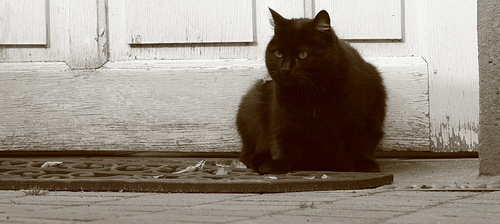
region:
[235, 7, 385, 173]
the cat lying down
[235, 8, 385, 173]
the black cat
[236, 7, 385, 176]
the cat all alone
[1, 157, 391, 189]
the mat under the cat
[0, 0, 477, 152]
the wood behind the cat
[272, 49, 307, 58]
the eyes on the cat's face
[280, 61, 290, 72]
the nose on the cat's face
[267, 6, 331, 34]
the ears on the cat's head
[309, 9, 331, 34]
the ear on the cat's head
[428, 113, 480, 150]
the paint chipped off the wood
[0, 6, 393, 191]
Black cat sitting on a door mat.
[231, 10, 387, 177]
the black cat laying in front of the door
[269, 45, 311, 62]
the green eyes of the cat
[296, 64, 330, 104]
the whiskers ont he cats face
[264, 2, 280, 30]
hair in the ear of the cat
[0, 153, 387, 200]
the black placemat in front of the door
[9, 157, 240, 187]
the paper on the black doormat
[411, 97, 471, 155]
the white paint chipping off the door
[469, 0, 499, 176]
the cement wall next to the front door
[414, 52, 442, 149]
the line in the door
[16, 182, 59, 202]
the grass growing on the porch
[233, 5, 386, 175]
A cat on a mat.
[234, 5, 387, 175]
A cat by a door.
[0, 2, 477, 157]
Part of a door.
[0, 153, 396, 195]
A mat by a door.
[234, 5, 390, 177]
A black cat sitting down.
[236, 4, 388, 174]
A black cat by a door.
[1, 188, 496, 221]
Bricks on the ground.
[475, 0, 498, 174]
Part of a wall.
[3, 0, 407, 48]
Panels on a door.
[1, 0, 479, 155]
Part of a white door.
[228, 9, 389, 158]
this is a cat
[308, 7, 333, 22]
this is the ear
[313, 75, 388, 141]
the cat is black in color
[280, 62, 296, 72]
this is the nose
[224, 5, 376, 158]
the cat is sitted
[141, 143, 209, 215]
this is the floor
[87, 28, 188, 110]
this is the door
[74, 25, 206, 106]
the door is wooden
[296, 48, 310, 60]
this is the eye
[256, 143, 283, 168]
these are the legs